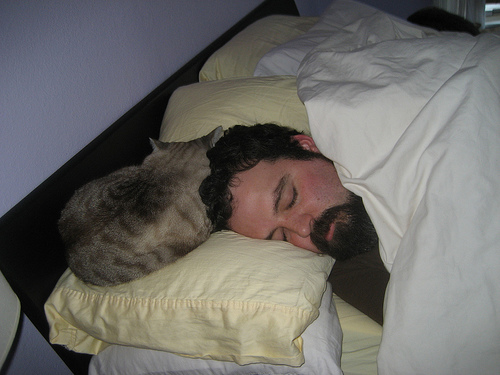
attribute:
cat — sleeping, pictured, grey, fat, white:
[58, 122, 229, 290]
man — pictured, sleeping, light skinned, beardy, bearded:
[198, 121, 391, 328]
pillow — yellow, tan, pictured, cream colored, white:
[41, 72, 338, 370]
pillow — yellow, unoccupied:
[194, 11, 321, 85]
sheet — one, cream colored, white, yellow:
[294, 7, 499, 374]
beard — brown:
[309, 189, 379, 262]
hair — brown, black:
[199, 121, 323, 237]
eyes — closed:
[265, 170, 300, 246]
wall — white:
[1, 0, 447, 373]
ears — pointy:
[145, 121, 226, 157]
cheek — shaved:
[300, 159, 346, 209]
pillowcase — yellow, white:
[40, 74, 338, 370]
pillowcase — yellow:
[195, 11, 326, 88]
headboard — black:
[1, 0, 308, 374]